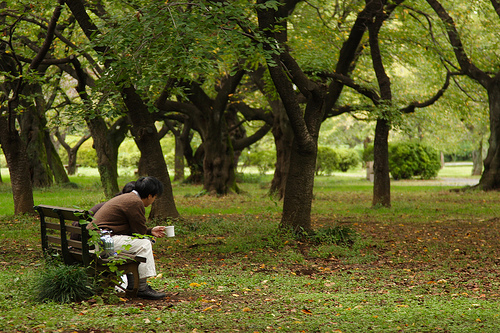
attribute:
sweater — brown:
[83, 190, 150, 232]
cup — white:
[157, 217, 182, 244]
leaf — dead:
[437, 278, 446, 283]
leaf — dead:
[401, 267, 412, 272]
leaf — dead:
[452, 247, 461, 252]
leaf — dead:
[422, 245, 427, 251]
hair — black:
[136, 174, 163, 199]